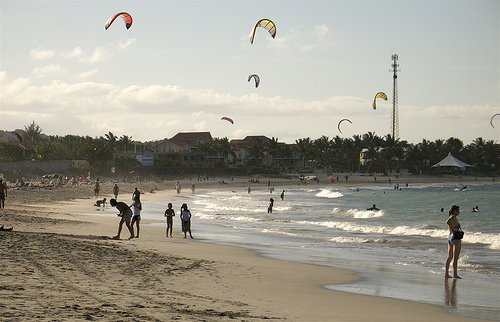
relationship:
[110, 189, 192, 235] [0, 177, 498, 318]
people above beach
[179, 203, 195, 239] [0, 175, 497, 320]
child standing in sand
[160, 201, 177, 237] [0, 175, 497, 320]
person standing in sand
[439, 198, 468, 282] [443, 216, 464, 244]
person in bikini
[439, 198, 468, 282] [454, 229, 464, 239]
person has bag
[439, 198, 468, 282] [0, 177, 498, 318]
person standing on beach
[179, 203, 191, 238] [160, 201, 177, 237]
child next to person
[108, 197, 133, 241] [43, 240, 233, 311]
man bent over in sand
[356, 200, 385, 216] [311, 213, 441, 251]
person in water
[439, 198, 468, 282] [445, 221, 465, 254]
person in bikini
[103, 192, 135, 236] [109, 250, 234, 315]
man crouching on beach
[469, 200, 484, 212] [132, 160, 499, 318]
people in water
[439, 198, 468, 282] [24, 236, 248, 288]
person standing on beach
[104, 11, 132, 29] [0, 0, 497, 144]
kite in sky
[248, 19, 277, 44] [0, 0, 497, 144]
kite in sky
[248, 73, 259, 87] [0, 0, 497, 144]
kite in sky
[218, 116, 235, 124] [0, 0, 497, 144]
kite in sky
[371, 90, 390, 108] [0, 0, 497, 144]
kite in sky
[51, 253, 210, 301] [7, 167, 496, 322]
sand on beach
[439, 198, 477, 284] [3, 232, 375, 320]
person on sand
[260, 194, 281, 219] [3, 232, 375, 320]
person on sand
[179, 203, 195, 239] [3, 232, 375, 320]
child on sand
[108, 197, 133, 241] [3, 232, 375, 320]
man on sand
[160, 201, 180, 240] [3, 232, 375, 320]
person on sand